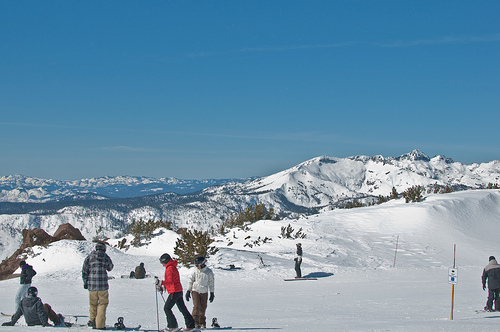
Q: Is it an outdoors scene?
A: Yes, it is outdoors.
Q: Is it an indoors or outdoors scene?
A: It is outdoors.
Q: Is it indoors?
A: No, it is outdoors.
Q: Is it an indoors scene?
A: No, it is outdoors.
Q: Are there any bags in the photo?
A: No, there are no bags.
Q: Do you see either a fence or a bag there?
A: No, there are no bags or fences.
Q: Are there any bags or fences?
A: No, there are no bags or fences.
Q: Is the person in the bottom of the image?
A: Yes, the person is in the bottom of the image.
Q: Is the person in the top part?
A: No, the person is in the bottom of the image.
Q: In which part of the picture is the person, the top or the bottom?
A: The person is in the bottom of the image.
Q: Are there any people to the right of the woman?
A: Yes, there is a person to the right of the woman.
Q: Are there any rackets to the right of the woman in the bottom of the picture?
A: No, there is a person to the right of the woman.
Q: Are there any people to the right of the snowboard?
A: Yes, there is a person to the right of the snowboard.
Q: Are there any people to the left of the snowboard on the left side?
A: No, the person is to the right of the snowboard.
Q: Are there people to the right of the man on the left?
A: Yes, there is a person to the right of the man.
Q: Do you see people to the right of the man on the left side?
A: Yes, there is a person to the right of the man.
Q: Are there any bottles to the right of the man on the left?
A: No, there is a person to the right of the man.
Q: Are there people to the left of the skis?
A: Yes, there is a person to the left of the skis.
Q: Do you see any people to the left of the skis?
A: Yes, there is a person to the left of the skis.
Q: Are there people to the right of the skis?
A: No, the person is to the left of the skis.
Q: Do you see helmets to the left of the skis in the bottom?
A: No, there is a person to the left of the skis.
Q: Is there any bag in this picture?
A: No, there are no bags.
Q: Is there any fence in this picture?
A: No, there are no fences.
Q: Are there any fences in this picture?
A: No, there are no fences.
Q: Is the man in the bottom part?
A: Yes, the man is in the bottom of the image.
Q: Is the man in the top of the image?
A: No, the man is in the bottom of the image.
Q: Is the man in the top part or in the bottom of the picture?
A: The man is in the bottom of the image.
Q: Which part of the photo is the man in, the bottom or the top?
A: The man is in the bottom of the image.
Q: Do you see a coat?
A: Yes, there is a coat.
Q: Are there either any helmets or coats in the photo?
A: Yes, there is a coat.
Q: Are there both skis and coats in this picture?
A: Yes, there are both a coat and skis.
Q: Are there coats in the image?
A: Yes, there is a coat.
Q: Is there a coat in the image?
A: Yes, there is a coat.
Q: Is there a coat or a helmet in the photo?
A: Yes, there is a coat.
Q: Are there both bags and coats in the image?
A: No, there is a coat but no bags.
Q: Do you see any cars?
A: No, there are no cars.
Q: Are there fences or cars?
A: No, there are no cars or fences.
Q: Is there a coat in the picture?
A: Yes, there is a coat.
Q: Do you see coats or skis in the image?
A: Yes, there is a coat.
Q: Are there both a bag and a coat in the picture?
A: No, there is a coat but no bags.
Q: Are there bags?
A: No, there are no bags.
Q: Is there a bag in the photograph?
A: No, there are no bags.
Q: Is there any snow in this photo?
A: Yes, there is snow.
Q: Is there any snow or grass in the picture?
A: Yes, there is snow.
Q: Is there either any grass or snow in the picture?
A: Yes, there is snow.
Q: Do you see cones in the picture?
A: No, there are no cones.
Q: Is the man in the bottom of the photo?
A: Yes, the man is in the bottom of the image.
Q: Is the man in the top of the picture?
A: No, the man is in the bottom of the image.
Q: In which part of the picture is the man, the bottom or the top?
A: The man is in the bottom of the image.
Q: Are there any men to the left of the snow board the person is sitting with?
A: Yes, there is a man to the left of the snowboard.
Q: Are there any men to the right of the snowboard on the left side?
A: No, the man is to the left of the snowboard.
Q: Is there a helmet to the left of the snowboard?
A: No, there is a man to the left of the snowboard.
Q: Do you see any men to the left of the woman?
A: Yes, there is a man to the left of the woman.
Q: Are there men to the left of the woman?
A: Yes, there is a man to the left of the woman.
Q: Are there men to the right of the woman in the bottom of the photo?
A: No, the man is to the left of the woman.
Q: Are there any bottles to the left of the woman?
A: No, there is a man to the left of the woman.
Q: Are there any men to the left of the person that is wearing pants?
A: Yes, there is a man to the left of the person.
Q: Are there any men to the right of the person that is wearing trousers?
A: No, the man is to the left of the person.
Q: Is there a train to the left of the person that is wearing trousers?
A: No, there is a man to the left of the person.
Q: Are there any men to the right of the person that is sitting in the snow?
A: Yes, there is a man to the right of the person.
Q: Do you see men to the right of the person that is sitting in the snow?
A: Yes, there is a man to the right of the person.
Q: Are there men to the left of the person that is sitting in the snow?
A: No, the man is to the right of the person.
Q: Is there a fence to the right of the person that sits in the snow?
A: No, there is a man to the right of the person.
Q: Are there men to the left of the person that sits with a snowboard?
A: Yes, there is a man to the left of the person.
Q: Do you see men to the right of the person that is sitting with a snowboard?
A: No, the man is to the left of the person.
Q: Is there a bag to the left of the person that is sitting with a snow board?
A: No, there is a man to the left of the person.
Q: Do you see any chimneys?
A: No, there are no chimneys.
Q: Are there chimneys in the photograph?
A: No, there are no chimneys.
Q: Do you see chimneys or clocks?
A: No, there are no chimneys or clocks.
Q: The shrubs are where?
A: The shrubs are on the mountain.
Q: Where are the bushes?
A: The shrubs are on the mountain.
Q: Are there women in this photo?
A: Yes, there is a woman.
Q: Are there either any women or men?
A: Yes, there is a woman.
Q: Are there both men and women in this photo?
A: Yes, there are both a woman and a man.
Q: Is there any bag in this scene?
A: No, there are no bags.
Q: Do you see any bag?
A: No, there are no bags.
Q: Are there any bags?
A: No, there are no bags.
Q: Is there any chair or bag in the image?
A: No, there are no bags or chairs.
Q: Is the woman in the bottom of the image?
A: Yes, the woman is in the bottom of the image.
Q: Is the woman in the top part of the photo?
A: No, the woman is in the bottom of the image.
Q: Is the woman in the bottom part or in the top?
A: The woman is in the bottom of the image.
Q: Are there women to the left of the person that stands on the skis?
A: Yes, there is a woman to the left of the person.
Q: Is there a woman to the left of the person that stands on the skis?
A: Yes, there is a woman to the left of the person.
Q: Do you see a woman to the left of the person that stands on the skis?
A: Yes, there is a woman to the left of the person.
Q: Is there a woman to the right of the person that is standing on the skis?
A: No, the woman is to the left of the person.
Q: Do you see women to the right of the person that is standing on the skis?
A: No, the woman is to the left of the person.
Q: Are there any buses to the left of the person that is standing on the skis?
A: No, there is a woman to the left of the person.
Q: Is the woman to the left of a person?
A: Yes, the woman is to the left of a person.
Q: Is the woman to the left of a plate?
A: No, the woman is to the left of a person.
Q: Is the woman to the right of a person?
A: No, the woman is to the left of a person.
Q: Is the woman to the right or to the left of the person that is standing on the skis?
A: The woman is to the left of the person.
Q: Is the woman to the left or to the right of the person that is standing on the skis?
A: The woman is to the left of the person.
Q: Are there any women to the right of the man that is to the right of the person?
A: Yes, there is a woman to the right of the man.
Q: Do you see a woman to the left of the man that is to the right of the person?
A: No, the woman is to the right of the man.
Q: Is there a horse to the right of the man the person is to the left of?
A: No, there is a woman to the right of the man.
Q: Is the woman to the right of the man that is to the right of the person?
A: Yes, the woman is to the right of the man.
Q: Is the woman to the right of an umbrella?
A: No, the woman is to the right of the man.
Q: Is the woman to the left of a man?
A: No, the woman is to the right of a man.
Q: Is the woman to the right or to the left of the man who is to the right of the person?
A: The woman is to the right of the man.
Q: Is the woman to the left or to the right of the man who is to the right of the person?
A: The woman is to the right of the man.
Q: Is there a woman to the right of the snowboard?
A: Yes, there is a woman to the right of the snowboard.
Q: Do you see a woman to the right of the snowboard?
A: Yes, there is a woman to the right of the snowboard.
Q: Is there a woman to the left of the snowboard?
A: No, the woman is to the right of the snowboard.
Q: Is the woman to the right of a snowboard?
A: Yes, the woman is to the right of a snowboard.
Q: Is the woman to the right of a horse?
A: No, the woman is to the right of a snowboard.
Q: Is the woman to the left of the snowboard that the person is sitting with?
A: No, the woman is to the right of the snowboard.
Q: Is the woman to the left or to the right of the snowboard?
A: The woman is to the right of the snowboard.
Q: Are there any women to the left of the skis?
A: Yes, there is a woman to the left of the skis.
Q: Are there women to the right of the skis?
A: No, the woman is to the left of the skis.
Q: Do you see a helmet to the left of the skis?
A: No, there is a woman to the left of the skis.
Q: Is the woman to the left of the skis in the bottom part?
A: Yes, the woman is to the left of the skis.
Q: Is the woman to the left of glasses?
A: No, the woman is to the left of the skis.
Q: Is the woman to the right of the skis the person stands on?
A: No, the woman is to the left of the skis.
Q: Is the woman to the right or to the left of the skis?
A: The woman is to the left of the skis.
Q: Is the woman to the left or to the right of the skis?
A: The woman is to the left of the skis.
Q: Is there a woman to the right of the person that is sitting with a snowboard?
A: Yes, there is a woman to the right of the person.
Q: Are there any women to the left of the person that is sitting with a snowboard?
A: No, the woman is to the right of the person.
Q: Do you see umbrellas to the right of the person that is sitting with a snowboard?
A: No, there is a woman to the right of the person.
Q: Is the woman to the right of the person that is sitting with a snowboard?
A: Yes, the woman is to the right of the person.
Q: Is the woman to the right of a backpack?
A: No, the woman is to the right of the person.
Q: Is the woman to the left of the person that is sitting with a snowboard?
A: No, the woman is to the right of the person.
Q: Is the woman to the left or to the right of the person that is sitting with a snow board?
A: The woman is to the right of the person.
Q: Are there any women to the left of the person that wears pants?
A: Yes, there is a woman to the left of the person.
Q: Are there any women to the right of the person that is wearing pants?
A: No, the woman is to the left of the person.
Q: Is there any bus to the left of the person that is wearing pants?
A: No, there is a woman to the left of the person.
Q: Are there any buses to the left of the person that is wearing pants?
A: No, there is a woman to the left of the person.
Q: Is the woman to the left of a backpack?
A: No, the woman is to the left of a person.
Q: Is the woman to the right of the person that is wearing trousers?
A: No, the woman is to the left of the person.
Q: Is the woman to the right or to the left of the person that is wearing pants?
A: The woman is to the left of the person.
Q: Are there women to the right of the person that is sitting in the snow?
A: Yes, there is a woman to the right of the person.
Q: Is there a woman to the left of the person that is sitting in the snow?
A: No, the woman is to the right of the person.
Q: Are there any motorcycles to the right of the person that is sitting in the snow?
A: No, there is a woman to the right of the person.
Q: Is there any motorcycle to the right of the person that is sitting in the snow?
A: No, there is a woman to the right of the person.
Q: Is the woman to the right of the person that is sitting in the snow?
A: Yes, the woman is to the right of the person.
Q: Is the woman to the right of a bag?
A: No, the woman is to the right of the person.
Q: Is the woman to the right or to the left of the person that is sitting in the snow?
A: The woman is to the right of the person.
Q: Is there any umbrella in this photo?
A: No, there are no umbrellas.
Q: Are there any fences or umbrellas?
A: No, there are no umbrellas or fences.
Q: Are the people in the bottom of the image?
A: Yes, the people are in the bottom of the image.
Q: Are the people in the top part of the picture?
A: No, the people are in the bottom of the image.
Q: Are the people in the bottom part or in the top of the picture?
A: The people are in the bottom of the image.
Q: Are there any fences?
A: No, there are no fences.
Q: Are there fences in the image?
A: No, there are no fences.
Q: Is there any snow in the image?
A: Yes, there is snow.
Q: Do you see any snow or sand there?
A: Yes, there is snow.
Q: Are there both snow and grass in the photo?
A: No, there is snow but no grass.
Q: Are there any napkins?
A: No, there are no napkins.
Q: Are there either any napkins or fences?
A: No, there are no napkins or fences.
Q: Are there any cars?
A: No, there are no cars.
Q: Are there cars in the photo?
A: No, there are no cars.